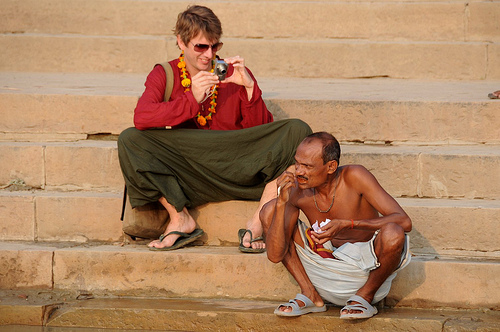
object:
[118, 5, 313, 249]
man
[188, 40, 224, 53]
sunglasses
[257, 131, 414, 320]
man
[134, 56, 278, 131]
shirt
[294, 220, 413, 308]
shorts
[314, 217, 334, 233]
object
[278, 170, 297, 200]
hand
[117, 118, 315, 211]
pants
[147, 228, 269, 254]
sandals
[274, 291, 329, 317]
sandals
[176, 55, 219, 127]
necklace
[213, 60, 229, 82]
camera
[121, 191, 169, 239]
bag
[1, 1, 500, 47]
steps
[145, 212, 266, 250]
feet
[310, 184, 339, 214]
necklace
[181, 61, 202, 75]
neck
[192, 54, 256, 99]
hands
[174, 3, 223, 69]
head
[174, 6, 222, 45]
hair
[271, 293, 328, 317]
sandal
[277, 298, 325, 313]
foot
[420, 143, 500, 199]
bricks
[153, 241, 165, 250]
toes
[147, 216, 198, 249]
foot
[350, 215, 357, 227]
bracelet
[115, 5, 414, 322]
men